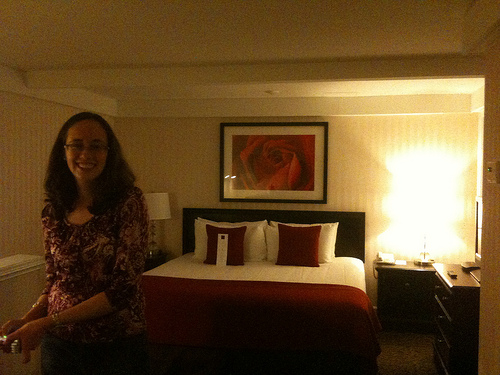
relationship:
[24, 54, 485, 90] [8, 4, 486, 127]
beam along ceiling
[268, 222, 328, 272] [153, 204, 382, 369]
pillow on bed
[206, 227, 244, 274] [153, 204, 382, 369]
pillow on bed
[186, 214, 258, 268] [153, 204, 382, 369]
pillow on bed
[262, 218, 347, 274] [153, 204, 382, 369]
pillow on bed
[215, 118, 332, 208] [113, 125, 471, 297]
painting on wall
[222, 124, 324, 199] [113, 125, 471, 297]
painting on wall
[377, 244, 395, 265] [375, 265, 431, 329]
phone on cabinet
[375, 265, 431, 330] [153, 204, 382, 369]
cabinet by bed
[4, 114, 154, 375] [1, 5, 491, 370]
woman standing in a bedroom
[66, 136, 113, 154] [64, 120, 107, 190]
glasses on her face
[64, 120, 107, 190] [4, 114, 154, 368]
face of woman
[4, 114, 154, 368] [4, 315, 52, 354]
woman has hands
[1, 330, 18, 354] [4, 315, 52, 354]
remote control in hands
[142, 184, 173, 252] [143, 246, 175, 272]
lamp on nightstand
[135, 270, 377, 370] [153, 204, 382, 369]
comforter laying on bed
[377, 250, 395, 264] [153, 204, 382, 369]
phone next to bed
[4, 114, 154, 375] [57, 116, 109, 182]
woman has face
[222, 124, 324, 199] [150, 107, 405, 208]
painting on wall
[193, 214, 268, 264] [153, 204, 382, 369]
pillow are on bed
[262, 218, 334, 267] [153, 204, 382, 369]
pillow are on bed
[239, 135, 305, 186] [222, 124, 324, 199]
rose in painting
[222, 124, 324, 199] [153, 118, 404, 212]
painting on wall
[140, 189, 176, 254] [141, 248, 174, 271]
lamp on table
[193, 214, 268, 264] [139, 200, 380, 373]
pillow are on bed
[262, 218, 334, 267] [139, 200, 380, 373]
pillow are on bed